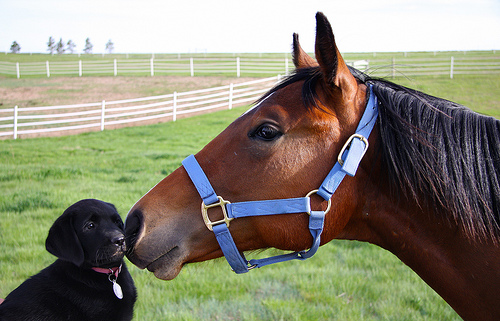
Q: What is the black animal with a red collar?
A: A puppy.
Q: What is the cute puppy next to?
A: A horse.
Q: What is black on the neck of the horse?
A: The mane.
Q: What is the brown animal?
A: The horse.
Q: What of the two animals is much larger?
A: The horse.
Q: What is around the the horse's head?
A: A blue strap.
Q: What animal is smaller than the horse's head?
A: The puppy.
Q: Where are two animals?
A: On a pasture.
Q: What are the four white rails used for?
A: Fencing.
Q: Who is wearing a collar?
A: The puppy.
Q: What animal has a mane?
A: The horse.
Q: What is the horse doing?
A: Sniffing the puppy.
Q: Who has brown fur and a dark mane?
A: The horse.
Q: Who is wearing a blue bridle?
A: The horse.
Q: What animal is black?
A: The puppy.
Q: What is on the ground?
A: Grass.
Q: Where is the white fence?
A: Behind the animals.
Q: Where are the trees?
A: In the distance behind the fence.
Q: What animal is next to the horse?
A: The puppy.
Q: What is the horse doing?
A: Kissing the puppy.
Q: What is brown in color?
A: A horse.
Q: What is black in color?
A: A puppy.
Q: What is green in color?
A: The grass.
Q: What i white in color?
A: A long fence.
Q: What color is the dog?
A: Black.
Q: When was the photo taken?
A: Day time.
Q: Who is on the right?
A: A horse.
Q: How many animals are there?
A: Two.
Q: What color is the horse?
A: Brown.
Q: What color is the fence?
A: White.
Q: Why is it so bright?
A: Sunny.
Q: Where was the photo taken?
A: On a ranch.